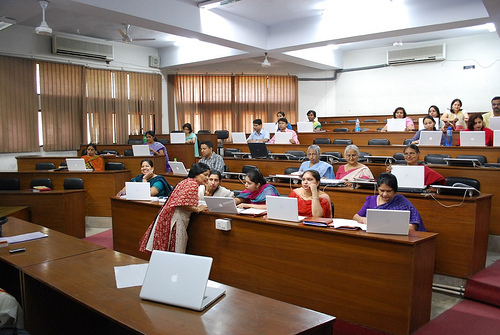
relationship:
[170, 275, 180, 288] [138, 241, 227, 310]
logo on laptop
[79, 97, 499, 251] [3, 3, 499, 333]
people in classroom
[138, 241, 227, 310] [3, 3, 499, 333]
laptop in classroom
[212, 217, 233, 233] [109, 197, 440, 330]
outlet on desk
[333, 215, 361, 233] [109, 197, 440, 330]
paper on desk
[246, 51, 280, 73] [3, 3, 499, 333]
fans in classroom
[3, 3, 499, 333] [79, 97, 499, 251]
classroom full of people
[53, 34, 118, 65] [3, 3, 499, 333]
conditioner in classroom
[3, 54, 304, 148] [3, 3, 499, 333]
windows in classroom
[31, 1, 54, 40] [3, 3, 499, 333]
light in classroom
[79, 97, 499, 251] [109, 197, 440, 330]
people at desk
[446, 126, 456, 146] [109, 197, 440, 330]
bottle on desk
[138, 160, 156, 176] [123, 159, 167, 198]
head of woman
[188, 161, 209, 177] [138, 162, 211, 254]
hair of people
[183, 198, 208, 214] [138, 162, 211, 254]
arm of people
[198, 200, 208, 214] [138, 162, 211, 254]
hand of people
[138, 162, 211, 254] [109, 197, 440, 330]
people leaning over desk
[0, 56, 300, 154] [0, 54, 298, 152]
curtains on window